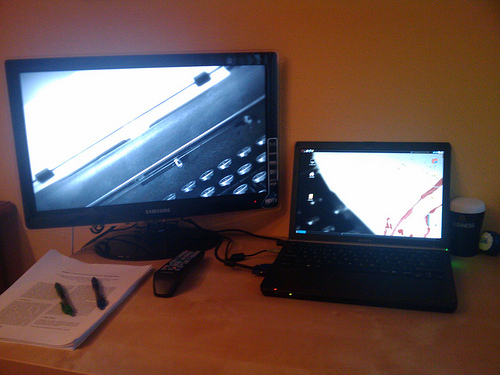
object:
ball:
[475, 227, 492, 251]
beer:
[447, 194, 488, 260]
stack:
[1, 250, 152, 352]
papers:
[5, 247, 150, 347]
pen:
[90, 275, 107, 310]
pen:
[53, 280, 73, 315]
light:
[440, 240, 450, 250]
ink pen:
[90, 275, 111, 312]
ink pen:
[52, 279, 72, 316]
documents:
[2, 233, 149, 365]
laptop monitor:
[269, 135, 471, 308]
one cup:
[447, 192, 488, 259]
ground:
[370, 90, 412, 139]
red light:
[250, 196, 260, 208]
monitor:
[21, 50, 306, 252]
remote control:
[146, 247, 223, 327]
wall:
[3, 0, 497, 197]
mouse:
[146, 241, 211, 302]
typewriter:
[308, 157, 440, 244]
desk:
[19, 202, 499, 372]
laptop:
[244, 110, 474, 330]